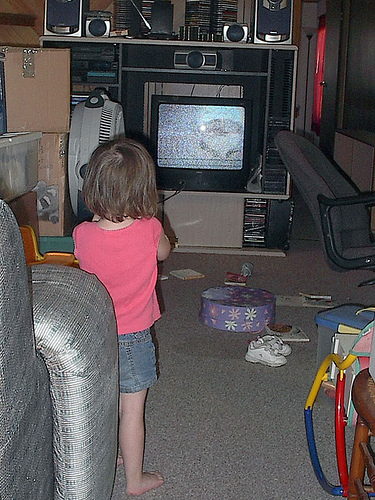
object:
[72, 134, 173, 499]
girl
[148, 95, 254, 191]
television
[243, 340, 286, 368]
tennis shoes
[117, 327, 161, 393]
shorts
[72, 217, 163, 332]
top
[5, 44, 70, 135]
cardboard boxes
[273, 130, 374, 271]
chair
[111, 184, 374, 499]
carpet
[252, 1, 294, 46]
speakers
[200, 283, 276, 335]
box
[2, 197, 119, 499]
couch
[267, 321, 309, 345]
book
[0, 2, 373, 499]
livingroom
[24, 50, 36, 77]
tape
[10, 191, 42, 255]
table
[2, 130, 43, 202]
box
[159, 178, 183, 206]
cables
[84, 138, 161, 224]
hair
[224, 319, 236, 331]
flowers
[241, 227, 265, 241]
dvds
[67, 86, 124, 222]
fan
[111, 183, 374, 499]
floor